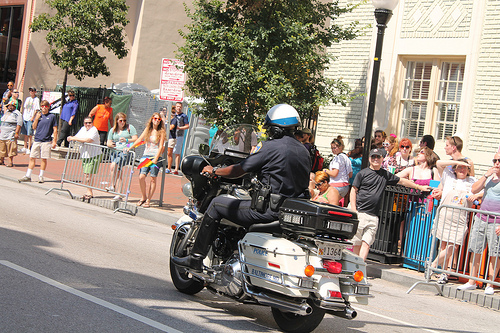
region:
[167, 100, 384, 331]
a cop on a motor cycle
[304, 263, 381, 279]
tail lights on a motorcycle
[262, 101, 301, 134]
a blue and white helmet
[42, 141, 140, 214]
a metal guard gate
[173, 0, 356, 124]
a leafy green tree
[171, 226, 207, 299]
front tire on a cycle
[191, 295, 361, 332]
a shadow under a bike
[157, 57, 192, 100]
a red and white sign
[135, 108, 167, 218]
This is a person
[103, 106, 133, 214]
This is a person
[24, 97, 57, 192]
This is a person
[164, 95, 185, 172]
This is a person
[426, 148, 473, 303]
This is a person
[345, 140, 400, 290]
This is a person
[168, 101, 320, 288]
This is a person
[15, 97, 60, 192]
This is a person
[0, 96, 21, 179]
This is a person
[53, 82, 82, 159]
This is a person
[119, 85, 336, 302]
he is on a motorbike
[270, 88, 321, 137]
he has a helmet on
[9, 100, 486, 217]
spectators watching the motorist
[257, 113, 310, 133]
helmet has a blue stripe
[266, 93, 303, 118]
his helmet is silver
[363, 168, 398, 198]
his shirt is black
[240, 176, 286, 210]
his utility belt is black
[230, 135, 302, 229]
wearing a police uniform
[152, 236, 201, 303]
the tires are black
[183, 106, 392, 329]
a policeman riding a motorcycle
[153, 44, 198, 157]
a street sign telling people what they can and cannot do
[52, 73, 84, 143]
person in blue standing against a fence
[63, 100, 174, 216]
a group of three people standing on sidewalk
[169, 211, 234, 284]
a boot on the left foot of policeman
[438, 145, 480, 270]
a female shielding her eyes from the sun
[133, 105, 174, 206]
a girl holding a flag in her hand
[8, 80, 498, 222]
people standing along the street watching a parade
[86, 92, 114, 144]
man wearing an orange tee shirt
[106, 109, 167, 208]
two women standing together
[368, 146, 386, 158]
black cap man is wearing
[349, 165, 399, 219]
black tee shirt man is wearing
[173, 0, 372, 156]
tree planted on the sidewalk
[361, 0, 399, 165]
black pole of the street light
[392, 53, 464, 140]
windows in the white building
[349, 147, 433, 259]
man leaning against the guard rail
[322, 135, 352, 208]
young girl looking at the street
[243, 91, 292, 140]
helmet on a head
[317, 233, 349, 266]
a license plate on the bike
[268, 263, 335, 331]
a tire on the bike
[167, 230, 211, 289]
a tire on the bike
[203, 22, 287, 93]
green leaves on the tree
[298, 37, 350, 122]
green leaves on the tree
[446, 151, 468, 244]
a person on the sidewalk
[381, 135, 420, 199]
a person on the sidewalk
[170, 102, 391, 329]
The cop is riding a motorcycle.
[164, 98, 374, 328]
The cops motorcycle is white and black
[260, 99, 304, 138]
The motorcycle helmet is blue and white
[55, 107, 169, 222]
The people are leaning on the gate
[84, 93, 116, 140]
The man is wearing an orange shirt.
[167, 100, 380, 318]
The motorcycle has red and yellow lights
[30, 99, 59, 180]
Man standing on a sidewalk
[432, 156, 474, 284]
Lady blocking out the sun